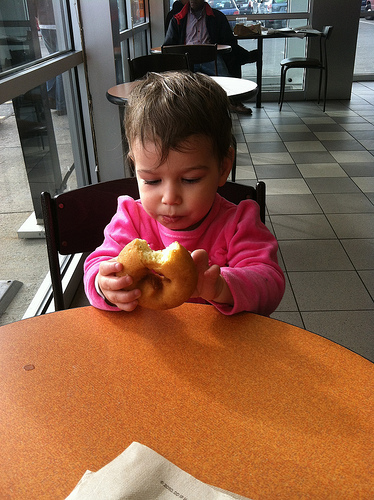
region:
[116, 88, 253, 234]
the head of a boy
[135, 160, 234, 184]
the eyes of a boy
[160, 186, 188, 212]
the nose of a boy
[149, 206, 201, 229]
the mouth of a boy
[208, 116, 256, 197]
the ear of a boy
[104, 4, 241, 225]
the hair of a baby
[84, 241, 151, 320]
the hand of a baby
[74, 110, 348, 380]
a baby sitting in a chair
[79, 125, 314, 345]
a baby wearing a shirt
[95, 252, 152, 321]
the fingers of a boy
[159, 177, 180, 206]
Nose on a little girl wearing pink.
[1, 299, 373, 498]
A round orange table a girl is sitting at.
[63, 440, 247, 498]
The grey edge of a newspaper on the orange table.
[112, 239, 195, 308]
A brown donut with a bite taken out.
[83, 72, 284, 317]
A little brown haired girl with a pink long sleeve sweater on.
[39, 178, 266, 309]
A black chair a girl in pink is sitting on.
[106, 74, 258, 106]
An empty orange and black table behind a girl.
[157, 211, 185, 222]
Red mouth of a little girl in pink.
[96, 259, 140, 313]
The little right hand of a girl.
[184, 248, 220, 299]
The little left hand of a little girl.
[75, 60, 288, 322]
Girl in pink shirt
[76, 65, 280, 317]
Girl in pink shirt with dougnut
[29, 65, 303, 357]
Girl sitting at orange table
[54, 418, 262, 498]
White napkin on orange table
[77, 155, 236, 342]
small child eating a doughnut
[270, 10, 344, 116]
Chair in a diner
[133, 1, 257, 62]
man in a dark blue jacket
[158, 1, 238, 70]
Man in a white shirt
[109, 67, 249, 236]
Young child with dark hair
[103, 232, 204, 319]
Doughnut with one bite taken out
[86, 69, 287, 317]
Young girl holding donut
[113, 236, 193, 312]
Small donut is bitten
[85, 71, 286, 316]
Young girl is sitting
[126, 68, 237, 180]
Hair is short and black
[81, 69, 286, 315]
Young girl wearing pink sweater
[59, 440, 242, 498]
Napkin in front of young girl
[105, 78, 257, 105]
Table behind young girl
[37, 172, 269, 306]
Chair girl is sitting on is black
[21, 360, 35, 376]
Small mark on table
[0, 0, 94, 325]
Window next to young girl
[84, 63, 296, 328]
a baby holding a donut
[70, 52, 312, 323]
the baby has short hair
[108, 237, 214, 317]
the donut is plain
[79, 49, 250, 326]
the baby took a bite of the donut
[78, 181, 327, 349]
the baby is wearing a pink sweater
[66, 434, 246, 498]
napkins made from recycled paper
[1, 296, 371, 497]
the table is round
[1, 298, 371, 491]
the table is orange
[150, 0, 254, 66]
a man is sitting at this table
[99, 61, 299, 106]
nobody is sitting at this table